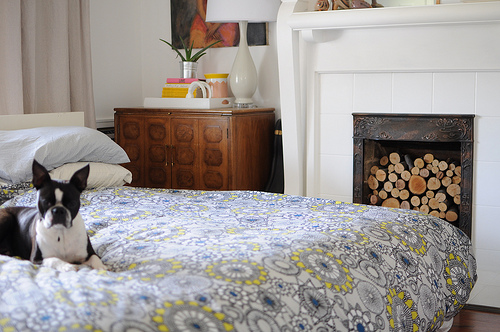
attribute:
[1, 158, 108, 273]
dog — white, black, lying down, looking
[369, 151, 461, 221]
wood — stacked, decoration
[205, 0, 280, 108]
lamp — tall, white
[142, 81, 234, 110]
tray — white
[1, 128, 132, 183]
pillow — stacked, light blue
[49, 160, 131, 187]
pillow — stacked, white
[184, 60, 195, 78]
tin — silver, plant holder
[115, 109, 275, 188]
furniture — wooden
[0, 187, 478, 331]
portion — yellow, blue, flowered, gray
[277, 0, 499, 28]
mantle — white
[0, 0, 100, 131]
curtain — white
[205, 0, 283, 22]
shade — white